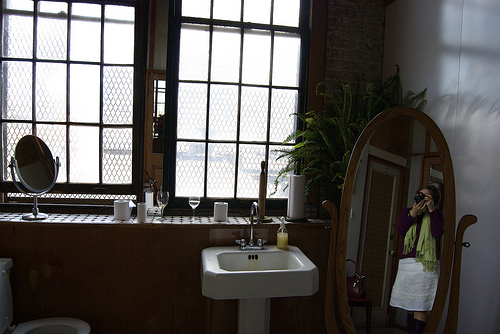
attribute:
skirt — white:
[391, 257, 438, 311]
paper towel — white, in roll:
[284, 174, 307, 219]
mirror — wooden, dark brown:
[6, 128, 66, 221]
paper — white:
[114, 199, 129, 218]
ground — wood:
[322, 127, 344, 165]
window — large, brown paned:
[171, 0, 306, 202]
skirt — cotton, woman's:
[387, 261, 439, 311]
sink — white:
[198, 240, 334, 332]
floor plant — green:
[283, 90, 426, 222]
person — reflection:
[386, 182, 453, 304]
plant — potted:
[269, 68, 432, 212]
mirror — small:
[11, 125, 61, 216]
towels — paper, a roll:
[258, 155, 322, 224]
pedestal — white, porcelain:
[236, 302, 271, 332]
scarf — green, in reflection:
[401, 215, 441, 272]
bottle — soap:
[278, 229, 292, 248]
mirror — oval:
[364, 153, 433, 285]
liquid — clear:
[184, 196, 201, 216]